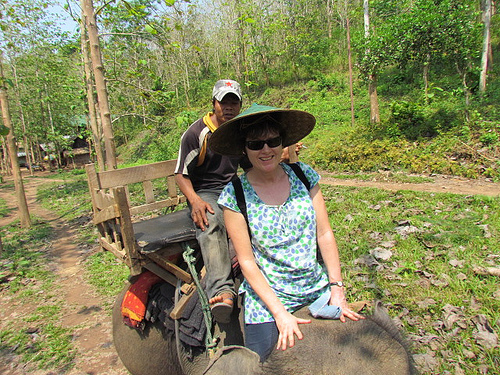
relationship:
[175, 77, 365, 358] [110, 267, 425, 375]
people on elephant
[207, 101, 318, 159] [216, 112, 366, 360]
hat on woman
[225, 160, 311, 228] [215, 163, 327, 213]
straps on shoulders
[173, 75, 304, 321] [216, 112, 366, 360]
man behind woman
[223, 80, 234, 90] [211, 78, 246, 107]
star on cap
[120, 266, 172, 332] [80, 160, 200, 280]
blanket under seat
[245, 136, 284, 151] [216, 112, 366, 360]
sunglasses on woman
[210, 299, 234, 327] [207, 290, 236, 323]
sandal on foot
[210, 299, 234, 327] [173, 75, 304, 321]
sandal on man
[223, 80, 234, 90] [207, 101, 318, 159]
star on hat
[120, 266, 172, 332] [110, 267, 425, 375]
blanket on elephant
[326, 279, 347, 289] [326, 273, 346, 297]
watch on wrist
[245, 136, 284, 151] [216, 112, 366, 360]
glasses on woman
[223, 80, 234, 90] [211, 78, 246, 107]
star on hat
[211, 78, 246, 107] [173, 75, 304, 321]
hat on man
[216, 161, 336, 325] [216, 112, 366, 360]
shirt on woman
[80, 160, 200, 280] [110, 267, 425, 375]
seat on elephant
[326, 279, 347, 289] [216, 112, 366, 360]
watch on woman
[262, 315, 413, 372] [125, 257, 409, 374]
fur on back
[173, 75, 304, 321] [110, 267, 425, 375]
man on elephant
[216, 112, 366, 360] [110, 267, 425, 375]
woman on elephant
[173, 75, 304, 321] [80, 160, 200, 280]
man on bench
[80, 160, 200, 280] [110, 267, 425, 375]
bench on elephant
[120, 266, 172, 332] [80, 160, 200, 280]
blanket under bench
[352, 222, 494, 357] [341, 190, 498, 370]
bark on grass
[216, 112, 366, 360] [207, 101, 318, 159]
woman wearing hat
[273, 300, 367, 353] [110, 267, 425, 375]
hands on elephant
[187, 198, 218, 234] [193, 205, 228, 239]
hand on knee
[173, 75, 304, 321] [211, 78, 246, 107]
man wearing cap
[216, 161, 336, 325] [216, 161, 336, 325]
shirt with design